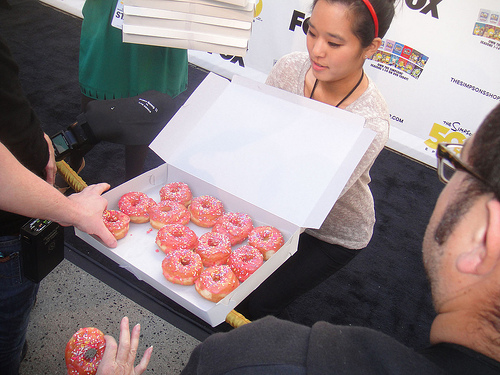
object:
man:
[175, 103, 498, 374]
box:
[72, 71, 376, 329]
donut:
[65, 324, 105, 373]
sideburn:
[434, 181, 484, 245]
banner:
[249, 0, 499, 157]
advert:
[288, 10, 429, 78]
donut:
[95, 210, 131, 240]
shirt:
[179, 314, 499, 374]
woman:
[238, 0, 390, 320]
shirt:
[254, 49, 391, 251]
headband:
[364, 0, 379, 40]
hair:
[433, 98, 498, 193]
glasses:
[434, 142, 495, 196]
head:
[419, 98, 499, 308]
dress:
[76, 0, 188, 103]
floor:
[342, 265, 424, 323]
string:
[310, 67, 365, 108]